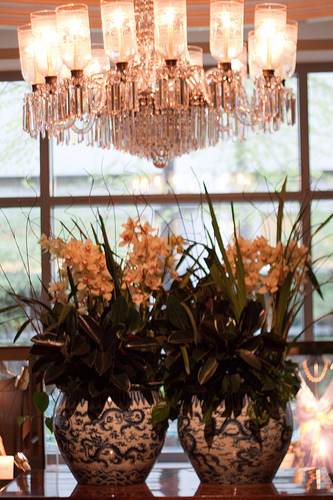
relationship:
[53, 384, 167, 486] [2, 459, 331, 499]
vase on table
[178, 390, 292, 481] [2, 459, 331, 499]
vase on table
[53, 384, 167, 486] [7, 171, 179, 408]
vase full of flowers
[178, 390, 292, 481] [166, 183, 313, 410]
vase full of flowers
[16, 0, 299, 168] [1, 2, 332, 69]
chandelier hanging from ceiling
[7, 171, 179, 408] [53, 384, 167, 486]
flowers in vase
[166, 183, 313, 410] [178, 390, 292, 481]
flowers in vase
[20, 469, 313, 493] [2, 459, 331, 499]
reflection of light on table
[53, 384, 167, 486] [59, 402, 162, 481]
vase has design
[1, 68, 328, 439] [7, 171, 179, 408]
window behind flowers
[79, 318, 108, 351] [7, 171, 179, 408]
leaf of flowers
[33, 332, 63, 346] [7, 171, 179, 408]
leaf of flowers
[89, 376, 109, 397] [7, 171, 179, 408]
leaf of flowers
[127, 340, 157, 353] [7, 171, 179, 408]
leaf of flowers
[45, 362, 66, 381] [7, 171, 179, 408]
leaf of flowers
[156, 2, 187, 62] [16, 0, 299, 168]
bulb guard on chandelier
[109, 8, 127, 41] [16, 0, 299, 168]
light bulb on chandelier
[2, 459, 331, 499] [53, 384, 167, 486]
table under vase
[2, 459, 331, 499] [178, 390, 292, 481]
table under vase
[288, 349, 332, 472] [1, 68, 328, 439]
mannequin reflection in window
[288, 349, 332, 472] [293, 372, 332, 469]
mannequin reflection has dress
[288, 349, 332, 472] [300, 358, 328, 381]
mannequin reflection has pearls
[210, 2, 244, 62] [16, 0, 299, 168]
glass flute on chandelier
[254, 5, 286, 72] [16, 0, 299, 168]
glass flute on chandelier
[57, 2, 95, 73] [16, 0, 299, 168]
glass flute on chandelier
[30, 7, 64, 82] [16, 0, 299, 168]
glass flute on chandelier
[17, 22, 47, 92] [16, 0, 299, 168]
glass flute on chandelier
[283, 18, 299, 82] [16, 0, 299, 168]
glass flute on chandelier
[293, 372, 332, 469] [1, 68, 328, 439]
dress reflected in window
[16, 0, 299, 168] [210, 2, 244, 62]
chandelier has glass flute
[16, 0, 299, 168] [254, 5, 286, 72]
chandelier has glass flute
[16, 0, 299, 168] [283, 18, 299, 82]
chandelier has glass flute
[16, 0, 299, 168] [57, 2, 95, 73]
chandelier has glass flute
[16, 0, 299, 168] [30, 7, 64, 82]
chandelier has glass flute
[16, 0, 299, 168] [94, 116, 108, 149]
chandelier has pendant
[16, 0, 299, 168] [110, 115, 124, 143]
chandelier has pendant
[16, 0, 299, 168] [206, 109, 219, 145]
chandelier has pendant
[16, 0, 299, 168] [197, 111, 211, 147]
chandelier has pendant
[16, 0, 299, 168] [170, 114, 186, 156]
chandelier has pendant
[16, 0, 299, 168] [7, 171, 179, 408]
chandelier hangs over flowers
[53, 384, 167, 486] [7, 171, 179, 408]
vase filled with flowers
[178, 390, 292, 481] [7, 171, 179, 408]
vase filled with flowers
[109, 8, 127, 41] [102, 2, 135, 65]
light bulb within bulb guard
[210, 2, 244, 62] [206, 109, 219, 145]
glass flute above pendant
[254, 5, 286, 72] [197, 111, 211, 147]
glass flute above pendant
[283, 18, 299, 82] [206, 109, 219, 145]
glass flute above pendant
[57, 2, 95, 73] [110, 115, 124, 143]
glass flute above pendant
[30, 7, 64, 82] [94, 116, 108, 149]
glass flute above pendant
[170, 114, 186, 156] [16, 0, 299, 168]
pendant at bottom of chandelier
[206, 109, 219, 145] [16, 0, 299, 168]
pendant at bottom of chandelier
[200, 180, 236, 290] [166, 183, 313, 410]
leaf in flowers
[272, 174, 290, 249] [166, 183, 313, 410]
leaf in flowers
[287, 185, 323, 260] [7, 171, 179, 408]
leaf in flowers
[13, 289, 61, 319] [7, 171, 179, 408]
leaf in flowers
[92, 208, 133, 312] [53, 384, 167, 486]
leaf hangs over vase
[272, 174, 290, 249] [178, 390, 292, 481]
leaf hangs over vase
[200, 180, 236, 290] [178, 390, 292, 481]
leaf hangs over vase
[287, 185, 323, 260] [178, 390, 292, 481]
leaf hangs over vase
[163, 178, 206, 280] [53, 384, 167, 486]
leaf hangs over vase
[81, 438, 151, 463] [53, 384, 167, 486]
dragon on vase